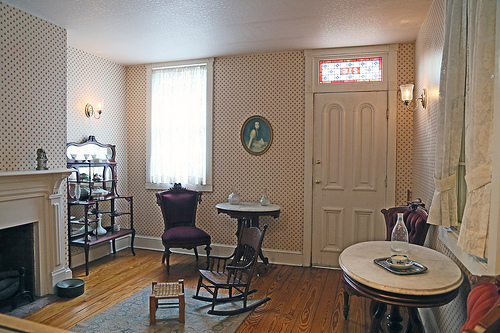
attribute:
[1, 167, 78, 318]
fireplace — white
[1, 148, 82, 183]
mantle — wooden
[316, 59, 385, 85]
window — stained glass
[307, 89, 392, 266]
door — white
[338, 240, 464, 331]
table — wooden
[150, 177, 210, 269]
chair — majestic, purple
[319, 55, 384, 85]
glass — red, blue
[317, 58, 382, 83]
glass window — stained glass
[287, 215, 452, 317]
table — glass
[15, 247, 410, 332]
floor — smooth, brown, hardwood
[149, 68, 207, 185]
curtain — white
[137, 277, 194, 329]
stand — short, brown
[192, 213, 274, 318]
chair — wooden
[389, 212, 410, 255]
glass bottle — clear